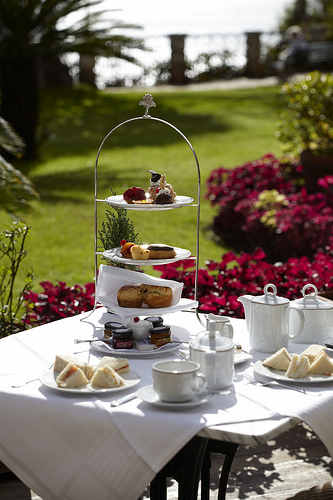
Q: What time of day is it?
A: Afternoon.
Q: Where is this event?
A: In the yard.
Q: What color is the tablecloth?
A: White.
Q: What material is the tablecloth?
A: Linen.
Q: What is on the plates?
A: Sandwiches.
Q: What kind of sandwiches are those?
A: Finger sandwiches.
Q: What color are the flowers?
A: Red.